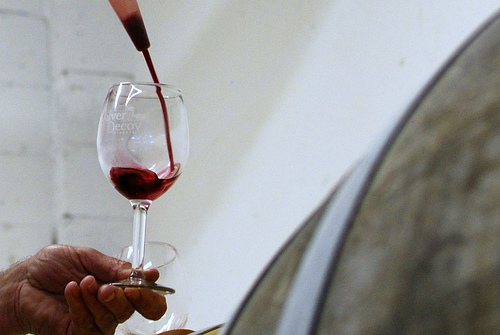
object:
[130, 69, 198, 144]
wine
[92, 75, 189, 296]
glass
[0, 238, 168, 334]
hand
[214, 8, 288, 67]
wall